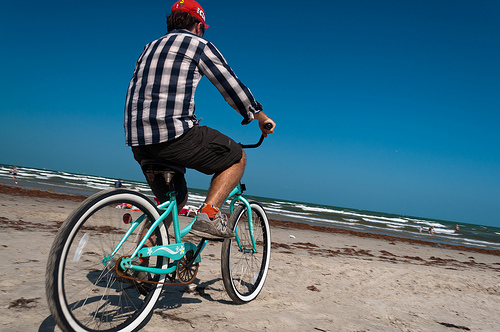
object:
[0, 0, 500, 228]
clear sky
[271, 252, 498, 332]
sand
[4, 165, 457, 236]
waves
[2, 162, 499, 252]
water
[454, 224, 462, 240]
people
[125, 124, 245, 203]
shorts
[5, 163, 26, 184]
people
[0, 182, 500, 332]
beach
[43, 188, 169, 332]
tires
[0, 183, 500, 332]
ground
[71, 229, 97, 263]
reflector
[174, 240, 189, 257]
flower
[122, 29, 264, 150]
shirt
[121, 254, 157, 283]
sneaker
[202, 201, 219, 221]
sock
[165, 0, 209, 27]
baseball cap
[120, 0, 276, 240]
man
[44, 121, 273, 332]
bicycle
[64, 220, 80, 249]
rims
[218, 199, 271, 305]
tires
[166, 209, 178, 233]
frame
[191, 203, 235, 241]
shoe